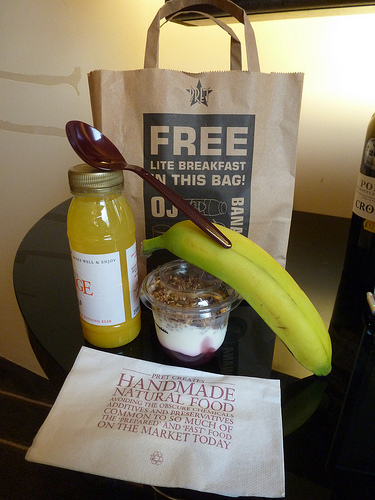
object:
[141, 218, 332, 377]
banana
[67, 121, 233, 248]
spoon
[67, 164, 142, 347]
bottle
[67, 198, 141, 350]
orange juice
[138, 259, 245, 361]
parfait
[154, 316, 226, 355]
yogurt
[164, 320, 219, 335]
fruit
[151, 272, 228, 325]
granola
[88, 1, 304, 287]
bag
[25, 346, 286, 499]
napkin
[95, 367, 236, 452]
print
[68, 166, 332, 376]
breakfast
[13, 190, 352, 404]
table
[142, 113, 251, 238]
print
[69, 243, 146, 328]
label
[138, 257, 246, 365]
cup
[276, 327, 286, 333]
spot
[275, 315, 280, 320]
spot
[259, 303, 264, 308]
spot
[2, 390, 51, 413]
line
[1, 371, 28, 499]
floor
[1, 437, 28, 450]
line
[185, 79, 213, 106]
star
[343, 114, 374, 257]
bottle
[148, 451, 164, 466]
symbol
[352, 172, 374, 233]
label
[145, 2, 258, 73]
handle